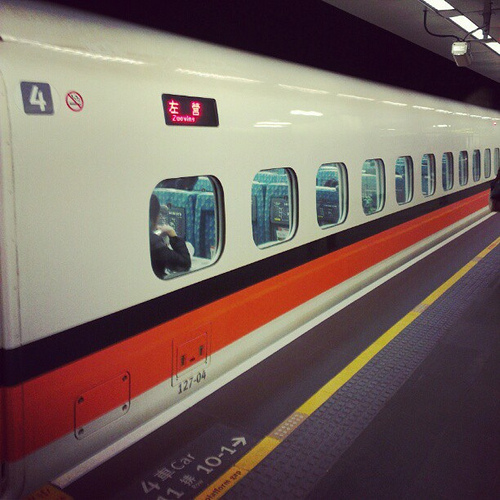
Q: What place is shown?
A: It is a sidewalk.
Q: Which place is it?
A: It is a sidewalk.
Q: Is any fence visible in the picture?
A: No, there are no fences.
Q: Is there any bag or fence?
A: No, there are no fences or bags.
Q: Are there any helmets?
A: No, there are no helmets.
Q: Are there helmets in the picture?
A: No, there are no helmets.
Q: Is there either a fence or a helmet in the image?
A: No, there are no helmets or fences.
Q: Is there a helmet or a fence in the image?
A: No, there are no helmets or fences.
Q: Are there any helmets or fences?
A: No, there are no helmets or fences.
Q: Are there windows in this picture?
A: Yes, there is a window.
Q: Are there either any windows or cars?
A: Yes, there is a window.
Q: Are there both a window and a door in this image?
A: No, there is a window but no doors.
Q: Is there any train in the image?
A: Yes, there is a train.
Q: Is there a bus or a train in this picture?
A: Yes, there is a train.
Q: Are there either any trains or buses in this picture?
A: Yes, there is a train.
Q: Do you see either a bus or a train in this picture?
A: Yes, there is a train.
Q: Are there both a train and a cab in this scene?
A: No, there is a train but no taxis.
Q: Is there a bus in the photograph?
A: No, there are no buses.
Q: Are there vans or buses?
A: No, there are no buses or vans.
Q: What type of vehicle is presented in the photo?
A: The vehicle is a train.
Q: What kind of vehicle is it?
A: The vehicle is a train.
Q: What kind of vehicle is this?
A: This is a train.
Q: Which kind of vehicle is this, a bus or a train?
A: This is a train.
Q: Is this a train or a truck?
A: This is a train.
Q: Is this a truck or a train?
A: This is a train.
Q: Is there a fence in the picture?
A: No, there are no fences.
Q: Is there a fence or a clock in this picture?
A: No, there are no fences or clocks.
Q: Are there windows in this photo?
A: Yes, there is a window.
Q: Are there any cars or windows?
A: Yes, there is a window.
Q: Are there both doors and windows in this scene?
A: No, there is a window but no doors.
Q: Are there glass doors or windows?
A: Yes, there is a glass window.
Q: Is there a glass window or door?
A: Yes, there is a glass window.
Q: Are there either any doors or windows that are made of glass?
A: Yes, the window is made of glass.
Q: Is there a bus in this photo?
A: No, there are no buses.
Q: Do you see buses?
A: No, there are no buses.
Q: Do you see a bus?
A: No, there are no buses.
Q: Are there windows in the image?
A: Yes, there is a window.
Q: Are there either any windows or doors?
A: Yes, there is a window.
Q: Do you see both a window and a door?
A: No, there is a window but no doors.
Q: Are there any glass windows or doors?
A: Yes, there is a glass window.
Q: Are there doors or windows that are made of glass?
A: Yes, the window is made of glass.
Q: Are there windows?
A: Yes, there is a window.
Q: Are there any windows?
A: Yes, there is a window.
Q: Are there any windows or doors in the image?
A: Yes, there is a window.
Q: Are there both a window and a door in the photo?
A: No, there is a window but no doors.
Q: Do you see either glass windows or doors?
A: Yes, there is a glass window.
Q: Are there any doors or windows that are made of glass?
A: Yes, the window is made of glass.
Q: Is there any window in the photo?
A: Yes, there is a window.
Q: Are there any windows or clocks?
A: Yes, there is a window.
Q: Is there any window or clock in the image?
A: Yes, there is a window.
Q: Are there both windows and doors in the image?
A: No, there is a window but no doors.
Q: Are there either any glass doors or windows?
A: Yes, there is a glass window.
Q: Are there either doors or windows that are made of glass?
A: Yes, the window is made of glass.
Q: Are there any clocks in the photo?
A: No, there are no clocks.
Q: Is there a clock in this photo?
A: No, there are no clocks.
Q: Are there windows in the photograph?
A: Yes, there is a window.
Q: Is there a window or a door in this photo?
A: Yes, there is a window.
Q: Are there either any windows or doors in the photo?
A: Yes, there is a window.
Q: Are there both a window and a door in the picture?
A: No, there is a window but no doors.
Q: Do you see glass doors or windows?
A: Yes, there is a glass window.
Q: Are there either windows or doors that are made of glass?
A: Yes, the window is made of glass.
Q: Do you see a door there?
A: No, there are no doors.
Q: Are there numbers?
A: Yes, there are numbers.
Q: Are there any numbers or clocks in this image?
A: Yes, there are numbers.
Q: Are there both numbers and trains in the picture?
A: Yes, there are both numbers and a train.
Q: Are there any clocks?
A: No, there are no clocks.